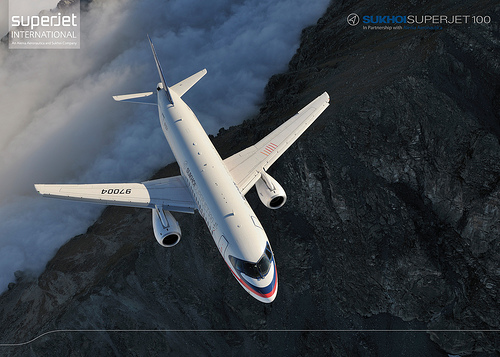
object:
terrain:
[1, 11, 485, 351]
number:
[118, 187, 132, 197]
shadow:
[169, 166, 239, 238]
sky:
[266, 0, 348, 55]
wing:
[225, 91, 333, 176]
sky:
[6, 20, 498, 355]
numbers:
[98, 188, 112, 195]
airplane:
[35, 32, 333, 302]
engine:
[149, 200, 184, 248]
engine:
[252, 169, 288, 209]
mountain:
[311, 71, 483, 251]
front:
[227, 261, 279, 302]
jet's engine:
[256, 171, 287, 208]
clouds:
[216, 30, 284, 83]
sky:
[20, 29, 405, 317]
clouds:
[16, 90, 111, 165]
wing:
[34, 174, 197, 210]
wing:
[168, 67, 207, 96]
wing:
[113, 87, 158, 105]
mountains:
[1, 3, 483, 352]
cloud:
[0, 0, 96, 58]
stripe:
[266, 143, 276, 152]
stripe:
[264, 144, 275, 152]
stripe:
[263, 145, 273, 154]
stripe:
[258, 149, 269, 156]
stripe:
[264, 145, 276, 155]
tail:
[110, 36, 207, 108]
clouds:
[238, 4, 287, 35]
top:
[31, 32, 330, 198]